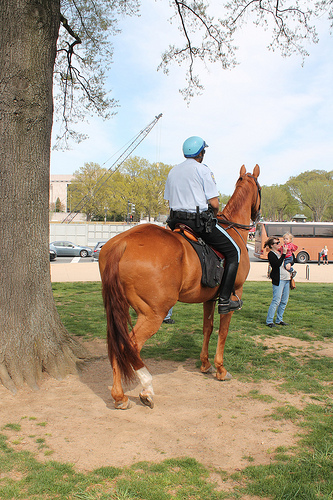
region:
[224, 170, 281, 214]
the head of a horse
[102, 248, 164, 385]
the tail of a horse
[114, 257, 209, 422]
the legs of a horse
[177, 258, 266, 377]
the front legs of a horse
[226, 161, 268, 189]
the ears of a horse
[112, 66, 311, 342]
a man on a horse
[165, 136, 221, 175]
a man wearing a helmet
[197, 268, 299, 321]
the foot of a man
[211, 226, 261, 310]
the leg of a man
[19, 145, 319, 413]
a horse near a tree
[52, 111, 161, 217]
crane in the air behind the wall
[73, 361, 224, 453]
dirt area by the tree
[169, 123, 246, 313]
police officer is on the horse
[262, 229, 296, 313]
woman is holding a little girl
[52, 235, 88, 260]
car is parked in a lot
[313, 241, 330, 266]
person is standing in front of a bus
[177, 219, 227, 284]
saddle on the horse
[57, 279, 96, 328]
green grass near the tree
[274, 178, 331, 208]
trees behind the building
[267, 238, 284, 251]
woman is wearing sunglasses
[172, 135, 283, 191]
the man is wearing a helmet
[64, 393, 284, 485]
dirt is on the ground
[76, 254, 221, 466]
the horse's tail is brown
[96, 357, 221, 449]
the horse has a white hoof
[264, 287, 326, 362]
the woman is wearing jeans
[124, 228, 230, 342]
the horse is brown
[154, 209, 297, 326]
the man is on a saddle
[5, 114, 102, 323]
the trunk is gray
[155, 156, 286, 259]
the man is wearing a white shirt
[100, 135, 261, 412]
police officer on a horse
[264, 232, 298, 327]
woman holding a little girl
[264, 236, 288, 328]
woman with blue jeans and a black sweater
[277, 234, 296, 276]
baby with a pink top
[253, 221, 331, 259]
an orange colored bus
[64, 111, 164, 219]
a construction crane in the background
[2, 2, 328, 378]
large tree beside officer on a horse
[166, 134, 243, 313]
police officer with a blue helmet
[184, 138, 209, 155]
a light blue helmet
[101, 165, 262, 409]
a light brown horse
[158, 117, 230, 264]
A policeman on the horse.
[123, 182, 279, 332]
The horse is standing by the tree.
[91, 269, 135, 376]
The horse has a long tail.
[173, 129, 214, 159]
The police office is wearing a blue helmet.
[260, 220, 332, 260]
A bus on the side of the road.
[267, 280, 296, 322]
The lady is wearing jeans.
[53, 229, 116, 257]
Cars on the street.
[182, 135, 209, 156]
helmet is worn by human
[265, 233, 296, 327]
Women standing on the grass holding her child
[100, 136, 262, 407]
Officer riding on a horse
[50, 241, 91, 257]
Light blue compact car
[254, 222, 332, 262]
Brown bus with tinted windows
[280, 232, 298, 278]
Child with red top and blue pants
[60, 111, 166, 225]
Crane arm in construction zone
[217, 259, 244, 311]
Black knee-high riding boots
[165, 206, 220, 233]
Security officer tool belt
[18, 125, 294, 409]
A horse standing beside a tree.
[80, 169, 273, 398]
A brown horse.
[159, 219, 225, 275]
A saddle on the back of a horse.